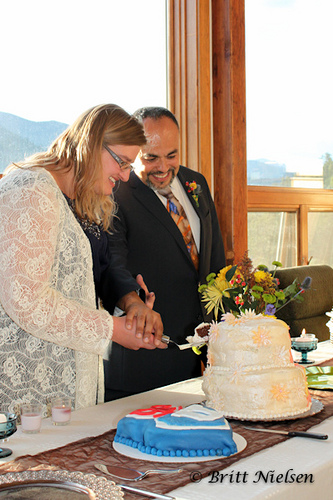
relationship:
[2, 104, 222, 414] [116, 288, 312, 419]
couple just married cutting the cake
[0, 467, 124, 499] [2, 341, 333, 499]
stainless steel platter on the table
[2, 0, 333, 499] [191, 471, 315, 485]
photo is copyright protected by britt nielsen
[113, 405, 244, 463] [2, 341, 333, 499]
blue cake on table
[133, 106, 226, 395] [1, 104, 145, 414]
groom holding knife with the bride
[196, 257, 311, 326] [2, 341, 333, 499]
bouquet of flowers on table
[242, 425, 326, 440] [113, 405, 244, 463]
sharp steak knife between two cakes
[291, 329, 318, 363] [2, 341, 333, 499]
green candle holder on table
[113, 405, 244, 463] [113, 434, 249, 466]
blue cake on a white plate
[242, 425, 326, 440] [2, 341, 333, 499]
sharp knife laying on table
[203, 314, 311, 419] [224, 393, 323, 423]
wedding cake on a silver platter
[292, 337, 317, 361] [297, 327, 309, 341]
candle holder green and has a lit candle in it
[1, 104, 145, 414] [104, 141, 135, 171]
bride wearing reading glasses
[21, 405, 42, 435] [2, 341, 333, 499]
two candle holders are on table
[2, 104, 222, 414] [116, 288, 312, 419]
bride and groom are celebrating by cutting the cake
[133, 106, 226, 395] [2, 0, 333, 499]
groom dressed for a wedding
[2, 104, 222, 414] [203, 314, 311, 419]
bride and groom are cutting cake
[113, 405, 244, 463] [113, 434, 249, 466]
blue cake on a porcelain plate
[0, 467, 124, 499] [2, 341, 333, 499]
silver platter on top of the table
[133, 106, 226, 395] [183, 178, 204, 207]
groom has a corsage on lapel of his jacket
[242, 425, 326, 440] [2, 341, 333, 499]
steak knife on top of tabel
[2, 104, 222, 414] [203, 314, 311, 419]
married couple are cutting cake together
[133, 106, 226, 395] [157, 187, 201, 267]
groom dressed in a suit and necktie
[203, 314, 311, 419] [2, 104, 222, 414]
wedding cake being cut by groom and bride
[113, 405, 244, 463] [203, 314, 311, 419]
second cake on table next to the wedding cake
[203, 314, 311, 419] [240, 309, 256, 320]
wedding cake white and has flowers on it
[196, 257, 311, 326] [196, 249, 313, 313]
bouquet has a colorful arrangement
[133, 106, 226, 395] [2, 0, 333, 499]
groom happy on h wedding day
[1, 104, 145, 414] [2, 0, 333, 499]
bride dressed for her wedding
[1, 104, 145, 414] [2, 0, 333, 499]
bride happy on her wedding day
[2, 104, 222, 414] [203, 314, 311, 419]
bride and groom are cutting their wedding cake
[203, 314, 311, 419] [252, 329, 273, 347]
cake white with orange flowers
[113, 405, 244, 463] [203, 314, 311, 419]
blue cake next to wedding cake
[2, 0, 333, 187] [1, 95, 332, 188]
picture windows open to mountains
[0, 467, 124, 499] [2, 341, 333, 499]
silver platter on edge of table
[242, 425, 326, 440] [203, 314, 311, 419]
sharp knife on table next to the wedding cake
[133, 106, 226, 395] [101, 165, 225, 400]
groom dressed with a suit and tie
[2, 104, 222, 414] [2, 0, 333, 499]
happy couple are celebrating their wedding